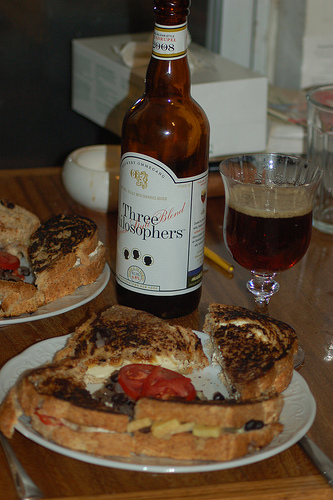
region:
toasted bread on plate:
[195, 299, 304, 472]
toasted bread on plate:
[76, 313, 247, 489]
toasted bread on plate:
[69, 304, 186, 438]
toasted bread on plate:
[221, 309, 331, 417]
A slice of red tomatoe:
[114, 359, 221, 413]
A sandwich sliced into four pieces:
[16, 285, 322, 464]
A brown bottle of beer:
[120, 3, 213, 316]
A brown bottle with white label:
[107, 3, 218, 316]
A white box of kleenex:
[62, 31, 274, 172]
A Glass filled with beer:
[217, 148, 320, 333]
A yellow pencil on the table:
[206, 245, 240, 278]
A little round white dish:
[61, 137, 153, 222]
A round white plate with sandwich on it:
[12, 327, 324, 479]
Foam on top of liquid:
[224, 183, 314, 223]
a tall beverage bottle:
[108, 1, 214, 321]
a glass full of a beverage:
[211, 151, 326, 318]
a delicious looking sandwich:
[10, 290, 318, 487]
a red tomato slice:
[105, 358, 199, 395]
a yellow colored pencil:
[199, 240, 232, 275]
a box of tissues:
[57, 26, 290, 153]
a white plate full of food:
[0, 319, 315, 479]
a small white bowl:
[61, 136, 132, 213]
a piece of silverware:
[0, 430, 48, 494]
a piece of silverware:
[299, 435, 328, 481]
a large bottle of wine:
[109, 3, 213, 315]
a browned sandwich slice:
[52, 300, 198, 381]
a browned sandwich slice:
[203, 300, 296, 399]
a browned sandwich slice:
[135, 394, 278, 463]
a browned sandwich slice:
[19, 357, 126, 458]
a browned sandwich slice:
[37, 204, 101, 305]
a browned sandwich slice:
[3, 280, 46, 313]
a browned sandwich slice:
[1, 203, 37, 249]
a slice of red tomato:
[116, 360, 194, 404]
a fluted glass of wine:
[217, 150, 318, 321]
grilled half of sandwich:
[208, 303, 302, 391]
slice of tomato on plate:
[118, 353, 199, 409]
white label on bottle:
[109, 142, 215, 303]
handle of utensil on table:
[4, 448, 39, 495]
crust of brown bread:
[45, 247, 98, 299]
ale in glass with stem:
[215, 153, 322, 302]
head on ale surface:
[224, 179, 316, 224]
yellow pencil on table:
[203, 246, 240, 280]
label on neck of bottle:
[141, 14, 197, 68]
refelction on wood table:
[294, 249, 327, 308]